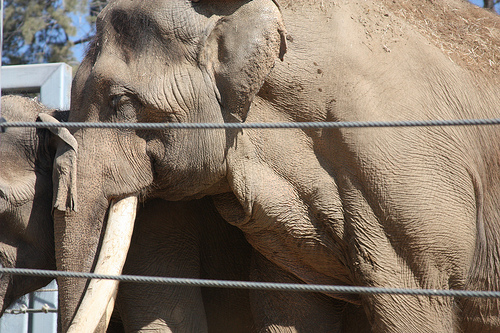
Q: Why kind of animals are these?
A: Elephants.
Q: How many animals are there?
A: Two.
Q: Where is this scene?
A: A zoo.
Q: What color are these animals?
A: Gray.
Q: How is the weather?
A: Sunny.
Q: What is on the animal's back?
A: Straw.